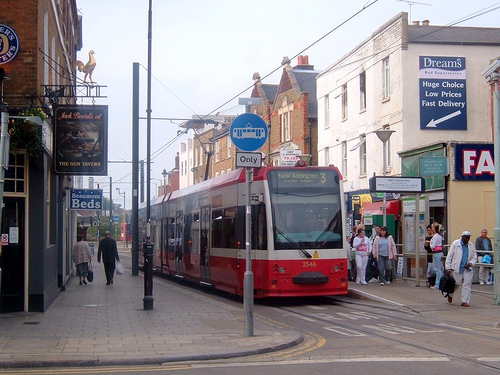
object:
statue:
[71, 50, 96, 83]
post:
[146, 5, 152, 308]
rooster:
[73, 49, 98, 83]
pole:
[41, 81, 106, 101]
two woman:
[422, 222, 444, 288]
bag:
[86, 258, 94, 282]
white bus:
[232, 122, 267, 140]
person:
[371, 226, 398, 287]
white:
[378, 176, 428, 190]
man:
[444, 230, 477, 305]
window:
[265, 167, 344, 248]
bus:
[133, 165, 348, 300]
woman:
[370, 225, 397, 285]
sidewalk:
[345, 266, 500, 312]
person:
[426, 222, 443, 290]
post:
[244, 167, 254, 334]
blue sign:
[228, 111, 270, 153]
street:
[0, 189, 500, 375]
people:
[73, 234, 92, 286]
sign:
[50, 100, 108, 178]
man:
[95, 229, 121, 286]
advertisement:
[419, 55, 467, 132]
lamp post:
[144, 1, 154, 309]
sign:
[223, 108, 269, 170]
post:
[237, 96, 257, 342]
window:
[175, 210, 183, 254]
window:
[162, 218, 176, 253]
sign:
[234, 151, 263, 168]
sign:
[70, 188, 103, 209]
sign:
[369, 175, 426, 194]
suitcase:
[437, 273, 456, 298]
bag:
[115, 258, 124, 276]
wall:
[403, 40, 491, 160]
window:
[210, 203, 267, 249]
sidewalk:
[0, 253, 298, 374]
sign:
[417, 55, 466, 132]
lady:
[348, 224, 373, 285]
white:
[445, 237, 476, 301]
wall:
[0, 0, 51, 319]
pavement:
[0, 249, 500, 375]